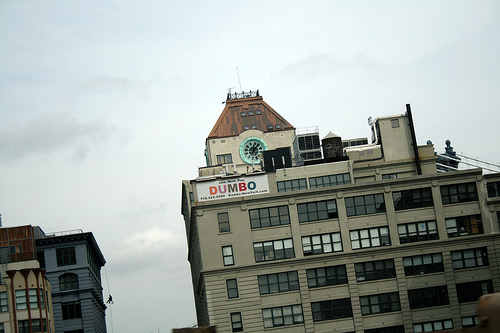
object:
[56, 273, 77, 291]
window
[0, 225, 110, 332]
building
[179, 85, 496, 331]
building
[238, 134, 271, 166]
window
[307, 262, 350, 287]
window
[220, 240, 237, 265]
window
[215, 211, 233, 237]
window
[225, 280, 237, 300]
window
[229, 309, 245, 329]
window